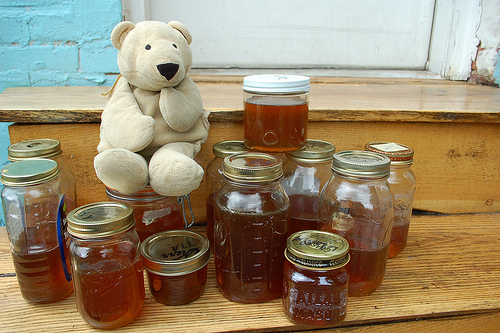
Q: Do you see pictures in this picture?
A: No, there are no pictures.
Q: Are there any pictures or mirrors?
A: No, there are no pictures or mirrors.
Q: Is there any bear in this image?
A: Yes, there is a bear.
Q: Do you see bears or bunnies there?
A: Yes, there is a bear.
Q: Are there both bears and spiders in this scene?
A: No, there is a bear but no spiders.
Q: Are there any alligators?
A: No, there are no alligators.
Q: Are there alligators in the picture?
A: No, there are no alligators.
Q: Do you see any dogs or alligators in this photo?
A: No, there are no alligators or dogs.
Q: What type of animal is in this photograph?
A: The animal is a bear.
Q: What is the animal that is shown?
A: The animal is a bear.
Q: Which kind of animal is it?
A: The animal is a bear.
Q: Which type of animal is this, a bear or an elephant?
A: This is a bear.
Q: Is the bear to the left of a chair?
A: No, the bear is to the left of a jar.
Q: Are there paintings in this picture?
A: No, there are no paintings.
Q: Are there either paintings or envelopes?
A: No, there are no paintings or envelopes.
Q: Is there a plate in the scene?
A: No, there are no plates.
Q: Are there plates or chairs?
A: No, there are no plates or chairs.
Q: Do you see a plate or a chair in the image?
A: No, there are no plates or chairs.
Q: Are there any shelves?
A: No, there are no shelves.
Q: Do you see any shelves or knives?
A: No, there are no shelves or knives.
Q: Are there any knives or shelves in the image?
A: No, there are no shelves or knives.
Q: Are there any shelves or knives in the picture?
A: No, there are no shelves or knives.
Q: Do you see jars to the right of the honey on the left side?
A: Yes, there is a jar to the right of the honey.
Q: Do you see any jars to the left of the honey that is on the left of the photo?
A: No, the jar is to the right of the honey.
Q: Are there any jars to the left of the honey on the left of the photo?
A: No, the jar is to the right of the honey.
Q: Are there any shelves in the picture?
A: No, there are no shelves.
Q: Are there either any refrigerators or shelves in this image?
A: No, there are no shelves or refrigerators.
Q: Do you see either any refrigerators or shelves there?
A: No, there are no shelves or refrigerators.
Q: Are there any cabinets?
A: No, there are no cabinets.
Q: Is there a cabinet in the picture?
A: No, there are no cabinets.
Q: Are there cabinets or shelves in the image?
A: No, there are no cabinets or shelves.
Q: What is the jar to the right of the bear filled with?
A: The jar is filled with liquid.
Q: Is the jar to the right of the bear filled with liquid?
A: Yes, the jar is filled with liquid.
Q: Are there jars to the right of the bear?
A: Yes, there is a jar to the right of the bear.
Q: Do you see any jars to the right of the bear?
A: Yes, there is a jar to the right of the bear.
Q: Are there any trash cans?
A: No, there are no trash cans.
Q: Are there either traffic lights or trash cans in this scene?
A: No, there are no trash cans or traffic lights.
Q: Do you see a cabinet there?
A: No, there are no cabinets.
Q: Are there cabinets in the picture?
A: No, there are no cabinets.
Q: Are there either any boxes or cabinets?
A: No, there are no cabinets or boxes.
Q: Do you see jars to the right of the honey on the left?
A: Yes, there is a jar to the right of the honey.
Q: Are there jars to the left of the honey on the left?
A: No, the jar is to the right of the honey.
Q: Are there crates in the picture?
A: No, there are no crates.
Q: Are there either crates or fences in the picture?
A: No, there are no crates or fences.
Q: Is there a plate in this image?
A: No, there are no plates.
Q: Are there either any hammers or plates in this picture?
A: No, there are no plates or hammers.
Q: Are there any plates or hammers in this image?
A: No, there are no plates or hammers.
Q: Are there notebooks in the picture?
A: No, there are no notebooks.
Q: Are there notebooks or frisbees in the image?
A: No, there are no notebooks or frisbees.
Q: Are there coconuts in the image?
A: No, there are no coconuts.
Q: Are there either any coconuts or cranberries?
A: No, there are no coconuts or cranberries.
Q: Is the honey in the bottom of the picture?
A: Yes, the honey is in the bottom of the image.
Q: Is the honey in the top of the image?
A: No, the honey is in the bottom of the image.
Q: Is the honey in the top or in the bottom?
A: The honey is in the bottom of the image.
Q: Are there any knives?
A: No, there are no knives.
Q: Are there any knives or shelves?
A: No, there are no knives or shelves.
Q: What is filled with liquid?
A: The jar is filled with liquid.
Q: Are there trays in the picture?
A: No, there are no trays.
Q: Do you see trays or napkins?
A: No, there are no trays or napkins.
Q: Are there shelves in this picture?
A: No, there are no shelves.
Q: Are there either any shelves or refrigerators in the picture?
A: No, there are no shelves or refrigerators.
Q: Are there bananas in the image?
A: No, there are no bananas.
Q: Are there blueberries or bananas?
A: No, there are no bananas or blueberries.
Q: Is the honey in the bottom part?
A: Yes, the honey is in the bottom of the image.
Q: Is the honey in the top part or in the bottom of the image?
A: The honey is in the bottom of the image.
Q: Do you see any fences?
A: No, there are no fences.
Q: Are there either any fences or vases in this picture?
A: No, there are no fences or vases.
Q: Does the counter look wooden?
A: Yes, the counter is wooden.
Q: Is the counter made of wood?
A: Yes, the counter is made of wood.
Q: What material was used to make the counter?
A: The counter is made of wood.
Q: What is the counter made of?
A: The counter is made of wood.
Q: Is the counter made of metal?
A: No, the counter is made of wood.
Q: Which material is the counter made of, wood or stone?
A: The counter is made of wood.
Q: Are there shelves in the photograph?
A: No, there are no shelves.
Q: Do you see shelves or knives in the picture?
A: No, there are no shelves or knives.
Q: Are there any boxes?
A: No, there are no boxes.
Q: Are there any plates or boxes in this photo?
A: No, there are no boxes or plates.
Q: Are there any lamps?
A: No, there are no lamps.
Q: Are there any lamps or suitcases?
A: No, there are no lamps or suitcases.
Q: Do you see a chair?
A: No, there are no chairs.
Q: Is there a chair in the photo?
A: No, there are no chairs.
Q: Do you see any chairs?
A: No, there are no chairs.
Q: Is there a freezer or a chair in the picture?
A: No, there are no chairs or refrigerators.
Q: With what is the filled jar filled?
A: The jar is filled with liquid.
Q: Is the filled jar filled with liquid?
A: Yes, the jar is filled with liquid.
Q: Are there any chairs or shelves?
A: No, there are no shelves or chairs.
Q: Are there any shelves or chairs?
A: No, there are no shelves or chairs.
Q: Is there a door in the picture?
A: Yes, there is a door.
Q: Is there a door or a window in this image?
A: Yes, there is a door.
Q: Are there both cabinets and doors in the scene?
A: No, there is a door but no cabinets.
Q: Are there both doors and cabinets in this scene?
A: No, there is a door but no cabinets.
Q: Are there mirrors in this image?
A: No, there are no mirrors.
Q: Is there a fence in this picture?
A: No, there are no fences.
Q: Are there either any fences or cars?
A: No, there are no fences or cars.